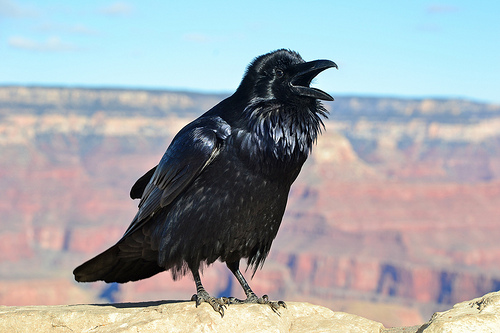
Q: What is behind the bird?
A: The inside of the mountain.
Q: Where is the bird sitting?
A: The bird is sitting on the mountain.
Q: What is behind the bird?
A: A large canyon.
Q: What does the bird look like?
A: The bird has black feathers.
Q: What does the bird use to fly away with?
A: With the wings.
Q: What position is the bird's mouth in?
A: The mouth is open.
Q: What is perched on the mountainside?
A: A black bird.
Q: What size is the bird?
A: The bird is a medium sized bird.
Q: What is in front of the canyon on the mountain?
A: A bird.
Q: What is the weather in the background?
A: The skies are blue with partial clouds.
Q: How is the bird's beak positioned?
A: Open.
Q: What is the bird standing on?
A: Rock.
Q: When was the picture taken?
A: When sun is out.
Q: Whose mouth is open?
A: Bird.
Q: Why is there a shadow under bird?
A: Sun.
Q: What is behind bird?
A: Canyon.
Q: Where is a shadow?
A: Under bird.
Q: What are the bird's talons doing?
A: Gripping rock.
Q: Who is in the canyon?
A: Black bird.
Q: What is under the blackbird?
A: A tan rock.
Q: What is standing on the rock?
A: A black crow.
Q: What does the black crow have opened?
A: Its beak.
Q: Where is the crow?
A: Standing on the rock.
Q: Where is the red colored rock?
A: On the canyon.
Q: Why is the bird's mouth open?
A: It is making noise.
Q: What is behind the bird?
A: The grand canyon.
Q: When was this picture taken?
A: During the day.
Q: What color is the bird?
A: Black.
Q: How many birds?
A: One.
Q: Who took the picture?
A: The photographer.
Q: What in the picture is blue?
A: The sky.